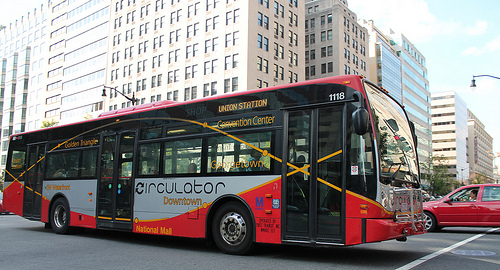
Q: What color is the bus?
A: Red, black, and gray.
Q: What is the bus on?
A: The road.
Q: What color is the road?
A: Gray.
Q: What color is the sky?
A: Blue.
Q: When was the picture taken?
A: Daytime.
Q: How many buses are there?
A: One.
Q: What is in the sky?
A: Clouds.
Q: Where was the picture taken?
A: On the street.